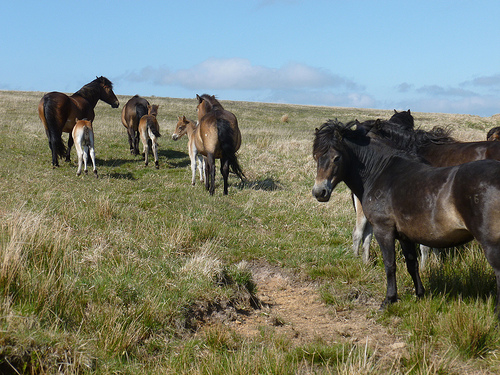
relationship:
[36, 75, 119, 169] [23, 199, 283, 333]
animal in field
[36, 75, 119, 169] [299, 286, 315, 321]
animal on dead grass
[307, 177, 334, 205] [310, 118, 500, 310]
nose of animal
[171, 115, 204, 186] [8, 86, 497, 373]
animal on grass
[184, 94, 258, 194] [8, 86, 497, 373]
horse on grass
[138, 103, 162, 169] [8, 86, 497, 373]
animal on grass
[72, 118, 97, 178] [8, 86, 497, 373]
animal on grass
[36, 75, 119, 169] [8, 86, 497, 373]
animal on grass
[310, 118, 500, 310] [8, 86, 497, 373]
animal on grass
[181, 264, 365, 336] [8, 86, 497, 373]
brown patch in grass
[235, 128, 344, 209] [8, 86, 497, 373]
grass patch in grass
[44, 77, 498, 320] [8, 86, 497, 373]
animals on grass